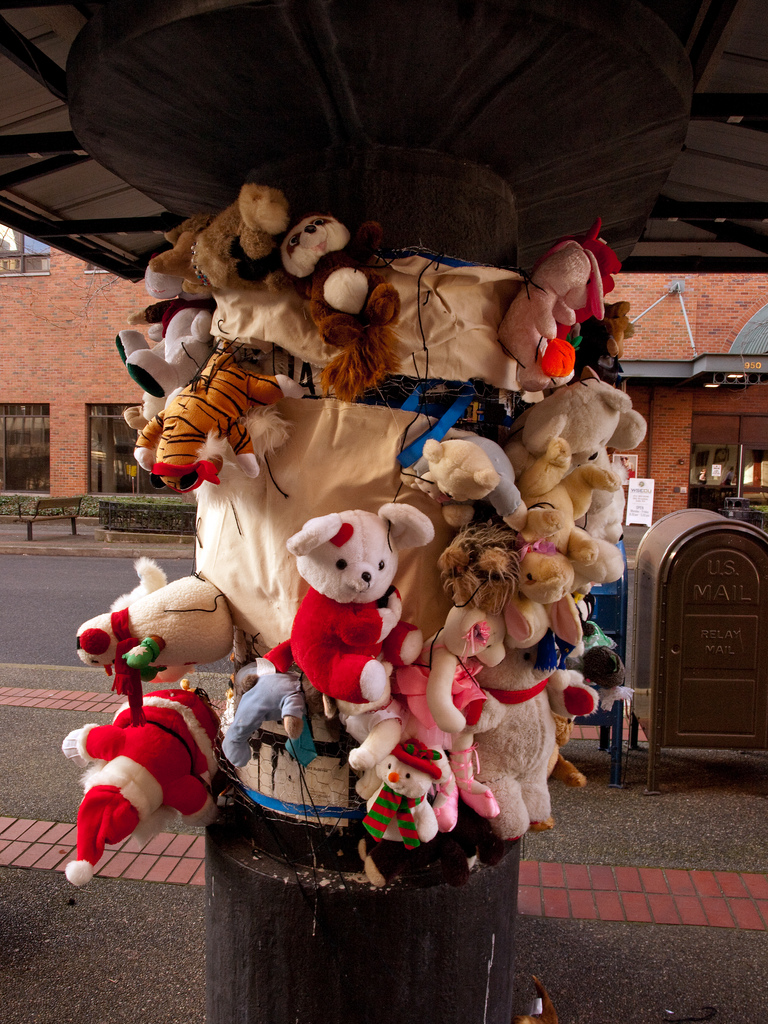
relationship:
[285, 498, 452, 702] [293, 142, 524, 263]
teddy bear on pole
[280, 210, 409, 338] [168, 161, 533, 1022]
teddy bear on pole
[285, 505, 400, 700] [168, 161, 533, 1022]
teddy bear on pole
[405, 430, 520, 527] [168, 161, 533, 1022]
teddy bear on pole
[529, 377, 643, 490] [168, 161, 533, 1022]
teddy bear on pole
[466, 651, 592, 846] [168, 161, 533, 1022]
teddy bear on pole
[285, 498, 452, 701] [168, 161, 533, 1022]
teddy bear on pole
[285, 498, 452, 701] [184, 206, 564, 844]
teddy bear on pole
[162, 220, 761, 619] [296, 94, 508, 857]
bear on pole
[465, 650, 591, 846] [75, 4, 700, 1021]
teddy bear on pole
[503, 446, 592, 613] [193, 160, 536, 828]
teddy bear on pole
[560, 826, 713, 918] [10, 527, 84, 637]
tile on ground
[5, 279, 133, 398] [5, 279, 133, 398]
bricks on building building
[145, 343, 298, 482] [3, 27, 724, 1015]
tiger attatched to object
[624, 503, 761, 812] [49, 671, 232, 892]
mailbox near stuffed animal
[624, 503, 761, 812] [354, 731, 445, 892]
mailbox near stuffed animal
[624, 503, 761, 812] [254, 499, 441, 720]
mailbox near stuffed animal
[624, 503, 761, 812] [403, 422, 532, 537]
mailbox near stuffed animal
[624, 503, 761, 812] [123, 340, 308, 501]
mailbox near stuffed animal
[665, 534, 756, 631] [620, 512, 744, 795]
words on mailbox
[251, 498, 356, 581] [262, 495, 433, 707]
ear of stuffed animal